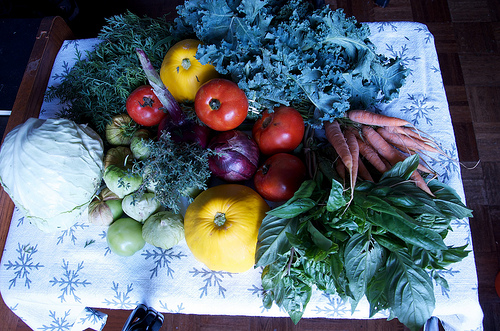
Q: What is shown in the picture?
A: Vegetables.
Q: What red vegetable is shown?
A: Tomatoes.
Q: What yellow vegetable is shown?
A: Squash.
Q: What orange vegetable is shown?
A: Carrots.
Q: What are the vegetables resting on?
A: A table.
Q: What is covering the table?
A: A tablecloth.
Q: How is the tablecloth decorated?
A: With snowflakes.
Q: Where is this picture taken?
A: A kitchen.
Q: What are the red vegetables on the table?
A: Tomatoes.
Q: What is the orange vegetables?
A: Carrots.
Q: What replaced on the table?
A: Vegetables.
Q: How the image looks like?
A: Good.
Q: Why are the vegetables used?
A: To eat.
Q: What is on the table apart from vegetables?
A: Cloth.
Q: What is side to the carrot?
A: Tomato.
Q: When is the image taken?
A: When vegetables are on table.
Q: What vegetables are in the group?
A: Tomatoes.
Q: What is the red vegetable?
A: Tomato.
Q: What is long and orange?
A: Carrots.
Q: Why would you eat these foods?
A: Healthy.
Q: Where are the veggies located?
A: On table.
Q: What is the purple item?
A: Onion.